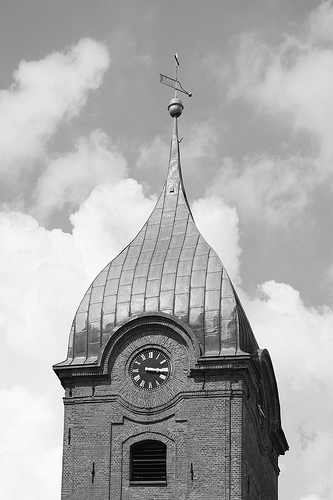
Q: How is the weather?
A: It is cloudy.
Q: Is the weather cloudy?
A: Yes, it is cloudy.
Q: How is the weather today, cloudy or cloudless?
A: It is cloudy.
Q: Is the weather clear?
A: No, it is cloudy.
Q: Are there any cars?
A: No, there are no cars.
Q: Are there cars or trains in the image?
A: No, there are no cars or trains.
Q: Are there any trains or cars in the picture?
A: No, there are no cars or trains.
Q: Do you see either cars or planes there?
A: No, there are no cars or planes.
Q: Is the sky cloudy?
A: Yes, the sky is cloudy.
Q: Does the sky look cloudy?
A: Yes, the sky is cloudy.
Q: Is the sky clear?
A: No, the sky is cloudy.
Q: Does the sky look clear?
A: No, the sky is cloudy.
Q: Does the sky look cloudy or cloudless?
A: The sky is cloudy.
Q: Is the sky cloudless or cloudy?
A: The sky is cloudy.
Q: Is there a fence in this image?
A: No, there are no fences.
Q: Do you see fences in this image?
A: No, there are no fences.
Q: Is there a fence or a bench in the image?
A: No, there are no fences or benches.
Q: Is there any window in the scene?
A: Yes, there is a window.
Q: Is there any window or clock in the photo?
A: Yes, there is a window.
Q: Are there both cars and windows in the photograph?
A: No, there is a window but no cars.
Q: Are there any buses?
A: No, there are no buses.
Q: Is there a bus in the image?
A: No, there are no buses.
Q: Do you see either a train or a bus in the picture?
A: No, there are no buses or trains.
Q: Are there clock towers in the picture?
A: Yes, there is a clock tower.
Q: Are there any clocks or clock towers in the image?
A: Yes, there is a clock tower.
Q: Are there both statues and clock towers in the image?
A: No, there is a clock tower but no statues.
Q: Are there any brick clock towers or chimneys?
A: Yes, there is a brick clock tower.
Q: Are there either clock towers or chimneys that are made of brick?
A: Yes, the clock tower is made of brick.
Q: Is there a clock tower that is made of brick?
A: Yes, there is a clock tower that is made of brick.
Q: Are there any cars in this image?
A: No, there are no cars.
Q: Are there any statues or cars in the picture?
A: No, there are no cars or statues.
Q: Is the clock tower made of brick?
A: Yes, the clock tower is made of brick.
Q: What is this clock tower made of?
A: The clock tower is made of brick.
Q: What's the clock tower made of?
A: The clock tower is made of brick.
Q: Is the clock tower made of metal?
A: No, the clock tower is made of brick.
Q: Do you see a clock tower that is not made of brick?
A: No, there is a clock tower but it is made of brick.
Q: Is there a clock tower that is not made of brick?
A: No, there is a clock tower but it is made of brick.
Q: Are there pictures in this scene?
A: No, there are no pictures.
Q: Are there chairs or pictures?
A: No, there are no pictures or chairs.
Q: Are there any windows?
A: Yes, there are windows.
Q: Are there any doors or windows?
A: Yes, there are windows.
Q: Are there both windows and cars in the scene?
A: No, there are windows but no cars.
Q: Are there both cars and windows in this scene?
A: No, there are windows but no cars.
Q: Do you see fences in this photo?
A: No, there are no fences.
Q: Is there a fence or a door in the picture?
A: No, there are no fences or doors.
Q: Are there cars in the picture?
A: No, there are no cars.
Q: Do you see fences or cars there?
A: No, there are no cars or fences.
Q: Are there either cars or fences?
A: No, there are no cars or fences.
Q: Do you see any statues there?
A: No, there are no statues.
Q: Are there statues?
A: No, there are no statues.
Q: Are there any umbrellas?
A: No, there are no umbrellas.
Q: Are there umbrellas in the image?
A: No, there are no umbrellas.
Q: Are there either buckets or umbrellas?
A: No, there are no umbrellas or buckets.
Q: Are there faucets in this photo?
A: No, there are no faucets.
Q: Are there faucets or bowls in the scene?
A: No, there are no faucets or bowls.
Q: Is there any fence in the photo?
A: No, there are no fences.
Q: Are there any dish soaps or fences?
A: No, there are no fences or dish soaps.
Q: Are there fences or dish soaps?
A: No, there are no fences or dish soaps.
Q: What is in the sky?
A: The clouds are in the sky.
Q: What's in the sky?
A: The clouds are in the sky.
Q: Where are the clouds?
A: The clouds are in the sky.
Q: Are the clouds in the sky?
A: Yes, the clouds are in the sky.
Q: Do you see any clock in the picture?
A: Yes, there is a clock.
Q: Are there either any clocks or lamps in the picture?
A: Yes, there is a clock.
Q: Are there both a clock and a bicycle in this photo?
A: No, there is a clock but no bicycles.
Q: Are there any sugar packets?
A: No, there are no sugar packets.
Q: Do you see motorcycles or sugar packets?
A: No, there are no sugar packets or motorcycles.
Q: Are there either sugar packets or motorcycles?
A: No, there are no sugar packets or motorcycles.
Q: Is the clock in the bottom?
A: Yes, the clock is in the bottom of the image.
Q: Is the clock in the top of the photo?
A: No, the clock is in the bottom of the image.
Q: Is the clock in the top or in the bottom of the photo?
A: The clock is in the bottom of the image.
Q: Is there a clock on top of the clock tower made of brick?
A: Yes, there is a clock on top of the clock tower.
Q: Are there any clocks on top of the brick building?
A: Yes, there is a clock on top of the clock tower.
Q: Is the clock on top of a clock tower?
A: Yes, the clock is on top of a clock tower.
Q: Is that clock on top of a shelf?
A: No, the clock is on top of a clock tower.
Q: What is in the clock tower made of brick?
A: The clock is in the clock tower.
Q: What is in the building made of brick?
A: The clock is in the clock tower.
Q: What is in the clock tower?
A: The clock is in the clock tower.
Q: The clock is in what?
A: The clock is in the clock tower.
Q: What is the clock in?
A: The clock is in the clock tower.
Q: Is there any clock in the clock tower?
A: Yes, there is a clock in the clock tower.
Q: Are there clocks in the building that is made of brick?
A: Yes, there is a clock in the clock tower.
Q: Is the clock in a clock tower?
A: Yes, the clock is in a clock tower.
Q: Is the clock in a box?
A: No, the clock is in a clock tower.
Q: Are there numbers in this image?
A: Yes, there are numbers.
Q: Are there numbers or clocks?
A: Yes, there are numbers.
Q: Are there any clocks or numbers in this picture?
A: Yes, there are numbers.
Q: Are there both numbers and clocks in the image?
A: Yes, there are both numbers and a clock.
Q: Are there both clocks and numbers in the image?
A: Yes, there are both numbers and a clock.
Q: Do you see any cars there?
A: No, there are no cars.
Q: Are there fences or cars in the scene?
A: No, there are no cars or fences.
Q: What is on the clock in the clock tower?
A: The numbers are on the clock.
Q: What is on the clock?
A: The numbers are on the clock.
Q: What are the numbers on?
A: The numbers are on the clock.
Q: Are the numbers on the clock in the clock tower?
A: Yes, the numbers are on the clock.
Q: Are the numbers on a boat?
A: No, the numbers are on the clock.